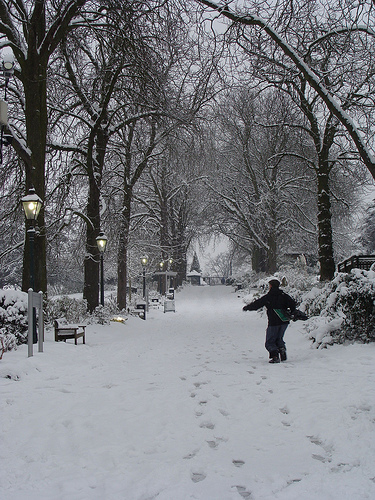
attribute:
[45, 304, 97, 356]
bench — snow covered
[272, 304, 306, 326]
snowboard — green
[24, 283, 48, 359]
sign — small, silver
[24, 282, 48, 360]
signpost — wooden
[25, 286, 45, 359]
banner — metallic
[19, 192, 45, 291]
lamp post — black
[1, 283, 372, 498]
snow — white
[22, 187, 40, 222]
lamp — bright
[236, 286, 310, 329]
coat — black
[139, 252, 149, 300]
lamp post — black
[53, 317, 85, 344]
bench — brown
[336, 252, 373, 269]
rail — wooden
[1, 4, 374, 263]
sky — white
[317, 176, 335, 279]
trunk — black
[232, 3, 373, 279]
tree — black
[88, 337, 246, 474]
patch — small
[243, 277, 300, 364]
person — average sized